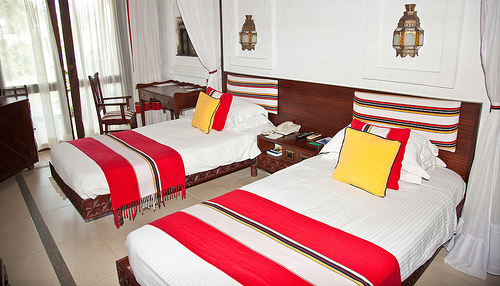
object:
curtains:
[0, 0, 72, 153]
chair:
[88, 72, 137, 136]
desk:
[133, 78, 208, 127]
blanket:
[62, 128, 188, 229]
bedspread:
[122, 153, 467, 286]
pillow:
[330, 127, 402, 199]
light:
[392, 26, 426, 57]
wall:
[157, 0, 484, 123]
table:
[250, 131, 322, 178]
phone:
[261, 120, 302, 135]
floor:
[0, 147, 271, 286]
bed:
[47, 116, 279, 223]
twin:
[150, 124, 355, 228]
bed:
[111, 153, 477, 286]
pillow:
[190, 90, 222, 134]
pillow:
[205, 86, 234, 132]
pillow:
[350, 118, 411, 190]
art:
[174, 16, 199, 58]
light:
[238, 28, 258, 47]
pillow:
[224, 97, 268, 128]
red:
[161, 155, 182, 180]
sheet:
[122, 152, 468, 285]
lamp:
[390, 3, 425, 58]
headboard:
[218, 71, 485, 184]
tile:
[54, 229, 119, 286]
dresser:
[0, 84, 39, 183]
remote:
[294, 130, 314, 140]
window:
[0, 0, 133, 152]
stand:
[266, 142, 284, 157]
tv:
[0, 56, 5, 104]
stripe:
[14, 172, 76, 285]